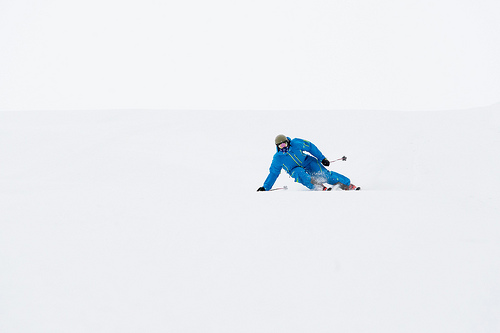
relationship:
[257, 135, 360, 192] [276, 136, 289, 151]
skier wearing helmet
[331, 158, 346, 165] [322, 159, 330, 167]
pole in hand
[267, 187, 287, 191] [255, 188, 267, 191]
pole in hand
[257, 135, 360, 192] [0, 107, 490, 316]
skier in snow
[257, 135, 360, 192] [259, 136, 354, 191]
skier wearing jacket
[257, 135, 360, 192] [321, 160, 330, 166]
skier wearing glove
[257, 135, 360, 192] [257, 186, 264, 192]
skier wearing glove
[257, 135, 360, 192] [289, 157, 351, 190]
skier wearing pants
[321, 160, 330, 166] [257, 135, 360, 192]
glove on skier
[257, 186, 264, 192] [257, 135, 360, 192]
glove on skier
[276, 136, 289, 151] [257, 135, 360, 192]
helmet on skier